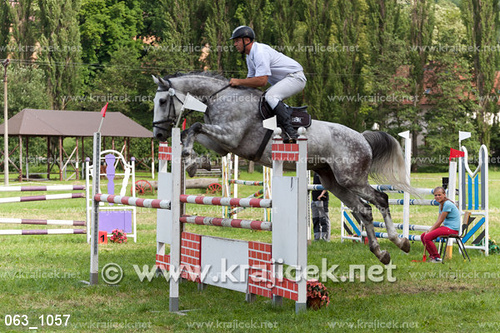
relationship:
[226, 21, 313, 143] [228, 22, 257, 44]
man wearing helmet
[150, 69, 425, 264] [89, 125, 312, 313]
horse jumping over barrier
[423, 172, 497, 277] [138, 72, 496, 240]
girl watching horse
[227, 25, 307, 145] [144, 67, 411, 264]
man riding horse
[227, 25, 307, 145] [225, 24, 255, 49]
man wearing helmet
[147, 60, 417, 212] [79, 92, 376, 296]
horse jumping hurdles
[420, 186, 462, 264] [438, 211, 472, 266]
girl sitting chair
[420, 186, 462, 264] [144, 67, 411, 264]
girl watching horse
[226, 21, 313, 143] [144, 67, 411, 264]
man riding horse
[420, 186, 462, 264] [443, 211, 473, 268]
girl sitting chair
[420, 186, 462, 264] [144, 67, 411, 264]
girl behind horse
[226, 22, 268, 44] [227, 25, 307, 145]
helmet worn by man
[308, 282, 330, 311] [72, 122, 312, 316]
flowers near barrier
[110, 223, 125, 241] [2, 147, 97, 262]
flowers near barrier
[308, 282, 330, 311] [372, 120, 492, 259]
flowers near barrier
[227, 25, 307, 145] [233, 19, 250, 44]
man wearing helmet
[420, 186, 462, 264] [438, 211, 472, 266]
girl sitting on chair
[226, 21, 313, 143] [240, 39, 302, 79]
man wearing white shirt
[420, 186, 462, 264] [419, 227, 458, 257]
girl wearing red pants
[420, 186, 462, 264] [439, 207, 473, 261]
girl sitting on chair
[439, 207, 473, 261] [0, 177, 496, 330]
chair sitting on lawn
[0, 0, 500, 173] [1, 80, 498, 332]
tree in training area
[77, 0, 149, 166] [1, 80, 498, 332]
tree in training area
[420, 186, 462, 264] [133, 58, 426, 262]
girl behind horse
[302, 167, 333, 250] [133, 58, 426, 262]
person behind horse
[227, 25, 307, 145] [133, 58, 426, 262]
man behind horse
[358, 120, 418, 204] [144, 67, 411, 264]
tail of horse